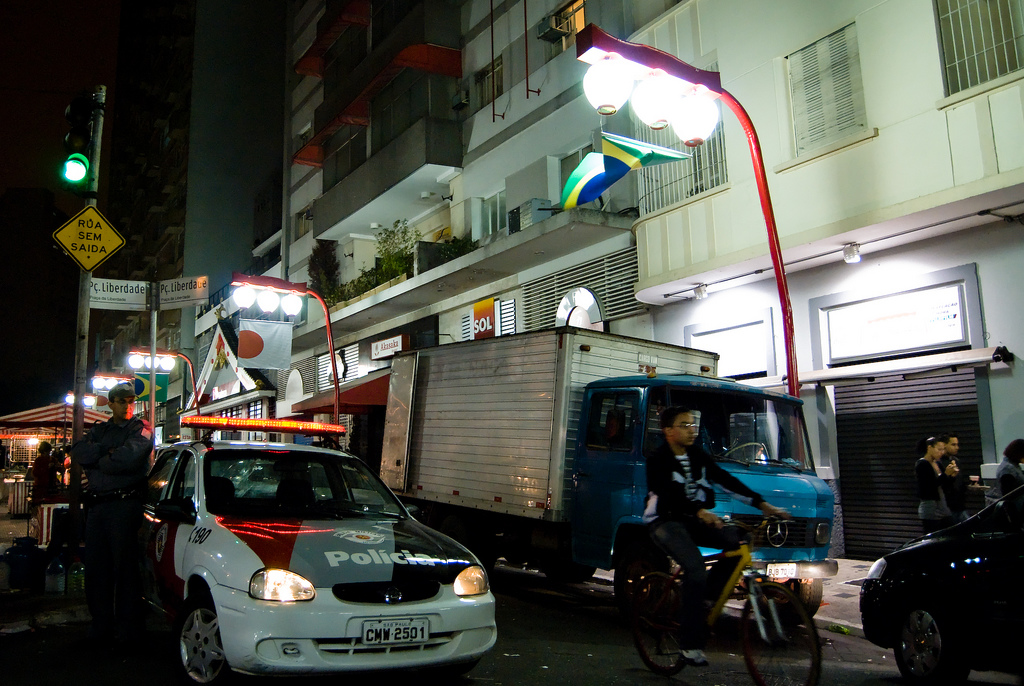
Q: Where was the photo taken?
A: On a street.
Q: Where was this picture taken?
A: On the street.